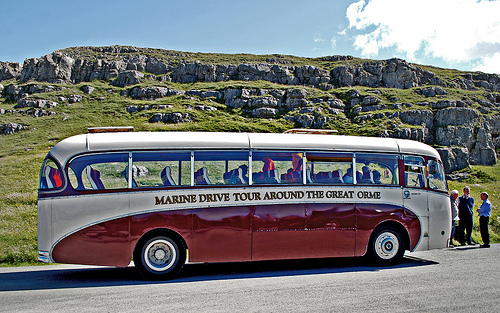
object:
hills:
[0, 44, 217, 125]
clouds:
[329, 0, 500, 77]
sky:
[1, 0, 314, 39]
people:
[449, 189, 460, 248]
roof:
[87, 126, 135, 134]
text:
[154, 190, 382, 206]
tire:
[132, 227, 186, 279]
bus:
[35, 125, 453, 280]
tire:
[368, 220, 407, 266]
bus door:
[397, 154, 430, 253]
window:
[37, 151, 65, 191]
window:
[128, 147, 194, 189]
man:
[456, 186, 476, 246]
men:
[476, 191, 492, 248]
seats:
[85, 164, 107, 191]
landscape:
[96, 55, 379, 122]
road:
[58, 276, 419, 313]